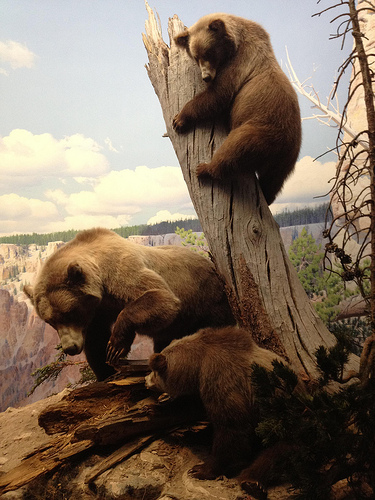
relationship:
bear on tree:
[170, 12, 302, 206] [116, 19, 338, 372]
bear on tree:
[170, 12, 302, 206] [136, 0, 348, 383]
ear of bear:
[206, 18, 226, 35] [170, 12, 302, 206]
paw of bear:
[193, 159, 224, 182] [170, 12, 302, 206]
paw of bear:
[172, 106, 191, 137] [170, 12, 302, 206]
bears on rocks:
[24, 13, 315, 481] [20, 315, 241, 497]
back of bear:
[86, 216, 246, 297] [225, 75, 325, 146]